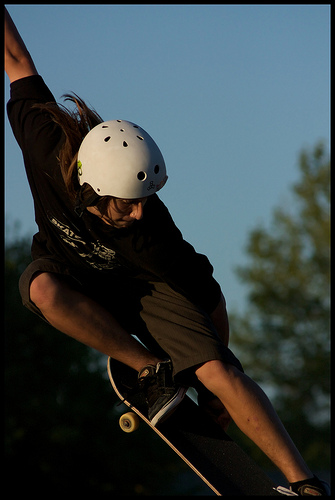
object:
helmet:
[72, 117, 168, 201]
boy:
[2, 1, 334, 499]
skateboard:
[107, 352, 292, 499]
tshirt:
[6, 75, 222, 315]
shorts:
[17, 254, 245, 372]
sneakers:
[136, 358, 187, 426]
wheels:
[118, 411, 143, 433]